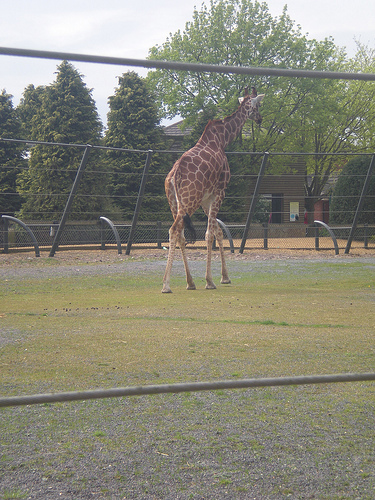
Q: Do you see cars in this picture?
A: No, there are no cars.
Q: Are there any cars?
A: No, there are no cars.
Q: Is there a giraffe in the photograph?
A: Yes, there is a giraffe.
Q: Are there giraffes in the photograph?
A: Yes, there is a giraffe.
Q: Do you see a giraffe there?
A: Yes, there is a giraffe.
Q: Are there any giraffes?
A: Yes, there is a giraffe.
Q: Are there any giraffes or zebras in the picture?
A: Yes, there is a giraffe.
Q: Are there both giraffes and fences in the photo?
A: Yes, there are both a giraffe and a fence.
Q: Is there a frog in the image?
A: No, there are no frogs.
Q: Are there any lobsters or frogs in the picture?
A: No, there are no frogs or lobsters.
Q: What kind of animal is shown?
A: The animal is a giraffe.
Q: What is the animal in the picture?
A: The animal is a giraffe.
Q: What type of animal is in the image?
A: The animal is a giraffe.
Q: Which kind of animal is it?
A: The animal is a giraffe.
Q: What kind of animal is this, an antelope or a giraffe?
A: This is a giraffe.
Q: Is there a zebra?
A: No, there are no zebras.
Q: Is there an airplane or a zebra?
A: No, there are no zebras or airplanes.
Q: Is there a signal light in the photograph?
A: No, there are no traffic lights.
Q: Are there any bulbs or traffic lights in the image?
A: No, there are no traffic lights or bulbs.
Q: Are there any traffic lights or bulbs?
A: No, there are no traffic lights or bulbs.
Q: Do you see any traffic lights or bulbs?
A: No, there are no traffic lights or bulbs.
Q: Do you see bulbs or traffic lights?
A: No, there are no traffic lights or bulbs.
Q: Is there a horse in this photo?
A: No, there are no horses.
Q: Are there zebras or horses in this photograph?
A: No, there are no horses or zebras.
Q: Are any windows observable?
A: Yes, there is a window.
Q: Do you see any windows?
A: Yes, there is a window.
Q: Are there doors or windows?
A: Yes, there is a window.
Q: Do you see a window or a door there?
A: Yes, there is a window.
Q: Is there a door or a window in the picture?
A: Yes, there is a window.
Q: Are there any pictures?
A: No, there are no pictures.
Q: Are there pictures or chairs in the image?
A: No, there are no pictures or chairs.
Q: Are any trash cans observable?
A: No, there are no trash cans.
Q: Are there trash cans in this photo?
A: No, there are no trash cans.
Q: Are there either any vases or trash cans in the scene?
A: No, there are no trash cans or vases.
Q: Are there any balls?
A: No, there are no balls.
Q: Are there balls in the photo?
A: No, there are no balls.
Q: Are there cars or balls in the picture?
A: No, there are no balls or cars.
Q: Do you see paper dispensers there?
A: No, there are no paper dispensers.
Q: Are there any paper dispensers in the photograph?
A: No, there are no paper dispensers.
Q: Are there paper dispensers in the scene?
A: No, there are no paper dispensers.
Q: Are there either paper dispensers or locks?
A: No, there are no paper dispensers or locks.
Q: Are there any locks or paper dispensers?
A: No, there are no paper dispensers or locks.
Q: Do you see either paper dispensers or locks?
A: No, there are no paper dispensers or locks.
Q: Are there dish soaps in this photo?
A: No, there are no dish soaps.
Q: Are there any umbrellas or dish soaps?
A: No, there are no dish soaps or umbrellas.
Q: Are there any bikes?
A: No, there are no bikes.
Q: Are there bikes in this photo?
A: No, there are no bikes.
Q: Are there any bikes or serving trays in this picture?
A: No, there are no bikes or serving trays.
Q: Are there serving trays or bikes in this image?
A: No, there are no bikes or serving trays.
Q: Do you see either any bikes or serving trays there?
A: No, there are no bikes or serving trays.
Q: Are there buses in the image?
A: No, there are no buses.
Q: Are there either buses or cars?
A: No, there are no buses or cars.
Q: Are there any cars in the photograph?
A: No, there are no cars.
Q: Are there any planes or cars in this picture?
A: No, there are no cars or planes.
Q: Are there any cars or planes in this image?
A: No, there are no cars or planes.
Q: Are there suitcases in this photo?
A: No, there are no suitcases.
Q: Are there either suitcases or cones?
A: No, there are no suitcases or cones.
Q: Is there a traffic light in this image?
A: No, there are no traffic lights.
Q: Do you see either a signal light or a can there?
A: No, there are no traffic lights or cans.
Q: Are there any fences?
A: Yes, there is a fence.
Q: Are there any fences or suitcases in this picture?
A: Yes, there is a fence.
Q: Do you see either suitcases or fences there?
A: Yes, there is a fence.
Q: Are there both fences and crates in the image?
A: No, there is a fence but no crates.